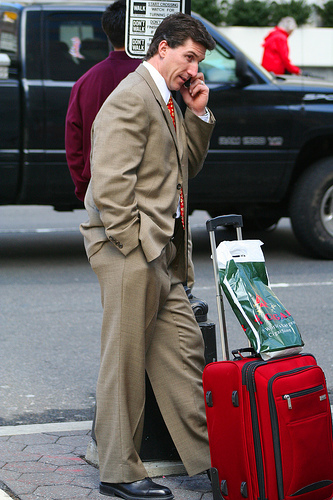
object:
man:
[77, 12, 216, 499]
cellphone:
[183, 75, 192, 89]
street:
[0, 219, 333, 424]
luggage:
[202, 213, 333, 497]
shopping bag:
[209, 237, 305, 362]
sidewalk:
[1, 423, 215, 499]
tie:
[166, 97, 185, 229]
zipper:
[283, 394, 292, 411]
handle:
[204, 214, 254, 364]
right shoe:
[98, 475, 175, 499]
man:
[64, 0, 154, 202]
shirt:
[64, 49, 142, 204]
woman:
[259, 16, 303, 74]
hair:
[277, 16, 297, 34]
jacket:
[260, 25, 300, 75]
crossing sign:
[125, 0, 187, 61]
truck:
[1, 2, 332, 263]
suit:
[79, 64, 215, 484]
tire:
[289, 156, 333, 259]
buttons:
[119, 244, 123, 249]